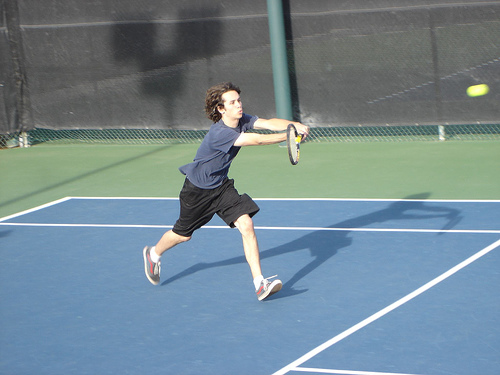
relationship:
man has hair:
[140, 79, 310, 303] [205, 82, 241, 121]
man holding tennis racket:
[140, 79, 310, 303] [288, 122, 311, 166]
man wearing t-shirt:
[140, 79, 310, 303] [179, 114, 257, 191]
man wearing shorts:
[140, 79, 310, 303] [172, 176, 258, 241]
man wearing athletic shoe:
[140, 79, 310, 303] [139, 244, 162, 283]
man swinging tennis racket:
[140, 79, 310, 303] [288, 122, 311, 166]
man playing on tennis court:
[140, 79, 310, 303] [1, 132, 499, 373]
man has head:
[140, 79, 310, 303] [205, 84, 242, 125]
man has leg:
[140, 79, 310, 303] [220, 189, 273, 285]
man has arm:
[140, 79, 310, 303] [214, 126, 289, 147]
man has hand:
[140, 79, 310, 303] [294, 123, 310, 135]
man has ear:
[140, 79, 310, 303] [216, 105, 226, 114]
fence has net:
[2, 2, 499, 139] [1, 2, 499, 141]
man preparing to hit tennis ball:
[140, 79, 310, 303] [467, 82, 488, 98]